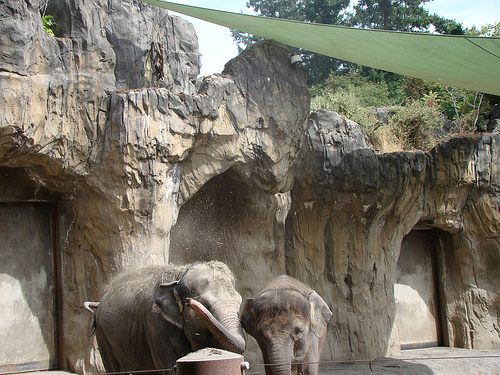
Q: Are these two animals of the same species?
A: Yes, all the animals are elephants.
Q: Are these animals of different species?
A: No, all the animals are elephants.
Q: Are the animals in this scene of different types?
A: No, all the animals are elephants.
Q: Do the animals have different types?
A: No, all the animals are elephants.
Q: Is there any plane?
A: No, there are no airplanes.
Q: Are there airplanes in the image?
A: No, there are no airplanes.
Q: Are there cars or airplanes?
A: No, there are no airplanes or cars.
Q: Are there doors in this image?
A: Yes, there is a door.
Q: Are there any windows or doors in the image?
A: Yes, there is a door.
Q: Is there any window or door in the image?
A: Yes, there is a door.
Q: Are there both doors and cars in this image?
A: No, there is a door but no cars.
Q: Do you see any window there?
A: No, there are no windows.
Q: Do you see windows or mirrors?
A: No, there are no windows or mirrors.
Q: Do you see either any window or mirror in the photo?
A: No, there are no windows or mirrors.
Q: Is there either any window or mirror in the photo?
A: No, there are no windows or mirrors.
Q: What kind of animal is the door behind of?
A: The door is behind the elephant.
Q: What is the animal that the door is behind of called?
A: The animal is an elephant.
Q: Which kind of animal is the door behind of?
A: The door is behind the elephant.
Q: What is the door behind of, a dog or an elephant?
A: The door is behind an elephant.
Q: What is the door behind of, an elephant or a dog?
A: The door is behind an elephant.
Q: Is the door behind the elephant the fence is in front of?
A: Yes, the door is behind the elephant.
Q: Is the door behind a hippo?
A: No, the door is behind the elephant.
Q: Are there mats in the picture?
A: No, there are no mats.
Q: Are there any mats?
A: No, there are no mats.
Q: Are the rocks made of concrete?
A: Yes, the rocks are made of concrete.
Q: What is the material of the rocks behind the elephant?
A: The rocks are made of cement.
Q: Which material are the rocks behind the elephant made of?
A: The rocks are made of cement.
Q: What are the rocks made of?
A: The rocks are made of concrete.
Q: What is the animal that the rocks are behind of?
A: The animal is an elephant.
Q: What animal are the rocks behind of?
A: The rocks are behind the elephant.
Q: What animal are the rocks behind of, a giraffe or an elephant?
A: The rocks are behind an elephant.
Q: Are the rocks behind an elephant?
A: Yes, the rocks are behind an elephant.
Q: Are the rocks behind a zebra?
A: No, the rocks are behind an elephant.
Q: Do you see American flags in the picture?
A: No, there are no American flags.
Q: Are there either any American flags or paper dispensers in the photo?
A: No, there are no American flags or paper dispensers.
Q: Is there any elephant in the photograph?
A: Yes, there is an elephant.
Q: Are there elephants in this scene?
A: Yes, there is an elephant.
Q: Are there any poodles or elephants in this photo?
A: Yes, there is an elephant.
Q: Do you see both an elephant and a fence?
A: Yes, there are both an elephant and a fence.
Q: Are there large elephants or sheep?
A: Yes, there is a large elephant.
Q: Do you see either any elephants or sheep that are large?
A: Yes, the elephant is large.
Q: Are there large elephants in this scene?
A: Yes, there is a large elephant.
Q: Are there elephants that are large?
A: Yes, there is an elephant that is large.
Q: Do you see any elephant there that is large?
A: Yes, there is an elephant that is large.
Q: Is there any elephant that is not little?
A: Yes, there is a large elephant.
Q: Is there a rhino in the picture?
A: No, there are no rhinos.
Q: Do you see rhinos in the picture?
A: No, there are no rhinos.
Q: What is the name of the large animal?
A: The animal is an elephant.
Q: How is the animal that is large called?
A: The animal is an elephant.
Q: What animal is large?
A: The animal is an elephant.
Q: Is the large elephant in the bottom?
A: Yes, the elephant is in the bottom of the image.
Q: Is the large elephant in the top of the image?
A: No, the elephant is in the bottom of the image.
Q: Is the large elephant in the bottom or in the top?
A: The elephant is in the bottom of the image.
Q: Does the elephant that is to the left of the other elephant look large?
A: Yes, the elephant is large.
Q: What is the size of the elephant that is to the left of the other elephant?
A: The elephant is large.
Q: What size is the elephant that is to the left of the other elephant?
A: The elephant is large.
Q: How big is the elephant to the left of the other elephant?
A: The elephant is large.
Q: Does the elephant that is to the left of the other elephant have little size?
A: No, the elephant is large.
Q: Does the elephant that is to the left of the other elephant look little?
A: No, the elephant is large.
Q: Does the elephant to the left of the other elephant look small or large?
A: The elephant is large.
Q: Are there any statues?
A: No, there are no statues.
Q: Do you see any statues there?
A: No, there are no statues.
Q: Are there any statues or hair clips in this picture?
A: No, there are no statues or hair clips.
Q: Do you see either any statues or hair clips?
A: No, there are no statues or hair clips.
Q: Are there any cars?
A: No, there are no cars.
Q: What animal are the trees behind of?
A: The trees are behind the elephant.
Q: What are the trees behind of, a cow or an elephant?
A: The trees are behind an elephant.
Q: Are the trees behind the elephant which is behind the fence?
A: Yes, the trees are behind the elephant.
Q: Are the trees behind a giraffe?
A: No, the trees are behind the elephant.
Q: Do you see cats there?
A: No, there are no cats.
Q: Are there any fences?
A: Yes, there is a fence.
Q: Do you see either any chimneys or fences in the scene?
A: Yes, there is a fence.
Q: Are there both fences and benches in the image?
A: No, there is a fence but no benches.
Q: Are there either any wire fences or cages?
A: Yes, there is a wire fence.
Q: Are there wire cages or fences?
A: Yes, there is a wire fence.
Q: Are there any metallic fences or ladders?
A: Yes, there is a metal fence.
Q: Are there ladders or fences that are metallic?
A: Yes, the fence is metallic.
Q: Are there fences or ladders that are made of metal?
A: Yes, the fence is made of metal.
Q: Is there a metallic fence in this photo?
A: Yes, there is a metal fence.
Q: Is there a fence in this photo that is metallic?
A: Yes, there is a fence that is metallic.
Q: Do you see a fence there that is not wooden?
A: Yes, there is a metallic fence.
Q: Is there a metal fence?
A: Yes, there is a fence that is made of metal.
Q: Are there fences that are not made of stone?
A: Yes, there is a fence that is made of metal.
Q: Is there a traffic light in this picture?
A: No, there are no traffic lights.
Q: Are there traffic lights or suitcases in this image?
A: No, there are no traffic lights or suitcases.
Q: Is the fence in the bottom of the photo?
A: Yes, the fence is in the bottom of the image.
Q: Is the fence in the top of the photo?
A: No, the fence is in the bottom of the image.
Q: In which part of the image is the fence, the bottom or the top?
A: The fence is in the bottom of the image.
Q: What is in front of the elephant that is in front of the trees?
A: The fence is in front of the elephant.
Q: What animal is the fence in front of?
A: The fence is in front of the elephant.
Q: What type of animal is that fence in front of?
A: The fence is in front of the elephant.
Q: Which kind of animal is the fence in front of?
A: The fence is in front of the elephant.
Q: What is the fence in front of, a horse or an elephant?
A: The fence is in front of an elephant.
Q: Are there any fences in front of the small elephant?
A: Yes, there is a fence in front of the elephant.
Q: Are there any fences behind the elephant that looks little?
A: No, the fence is in front of the elephant.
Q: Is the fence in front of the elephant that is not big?
A: Yes, the fence is in front of the elephant.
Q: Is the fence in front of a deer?
A: No, the fence is in front of the elephant.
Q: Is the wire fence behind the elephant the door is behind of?
A: No, the fence is in front of the elephant.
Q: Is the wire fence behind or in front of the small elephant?
A: The fence is in front of the elephant.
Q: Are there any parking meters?
A: No, there are no parking meters.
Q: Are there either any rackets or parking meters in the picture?
A: No, there are no parking meters or rackets.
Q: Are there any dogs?
A: No, there are no dogs.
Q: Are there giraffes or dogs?
A: No, there are no dogs or giraffes.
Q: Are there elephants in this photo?
A: Yes, there is an elephant.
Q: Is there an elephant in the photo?
A: Yes, there is an elephant.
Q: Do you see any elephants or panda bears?
A: Yes, there is an elephant.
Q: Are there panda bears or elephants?
A: Yes, there is an elephant.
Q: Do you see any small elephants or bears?
A: Yes, there is a small elephant.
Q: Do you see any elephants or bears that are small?
A: Yes, the elephant is small.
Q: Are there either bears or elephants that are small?
A: Yes, the elephant is small.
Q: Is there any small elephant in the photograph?
A: Yes, there is a small elephant.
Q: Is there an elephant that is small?
A: Yes, there is an elephant that is small.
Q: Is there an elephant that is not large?
A: Yes, there is a small elephant.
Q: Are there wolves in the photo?
A: No, there are no wolves.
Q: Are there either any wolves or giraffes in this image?
A: No, there are no wolves or giraffes.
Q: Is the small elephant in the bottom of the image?
A: Yes, the elephant is in the bottom of the image.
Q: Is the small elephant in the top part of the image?
A: No, the elephant is in the bottom of the image.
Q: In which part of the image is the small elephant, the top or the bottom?
A: The elephant is in the bottom of the image.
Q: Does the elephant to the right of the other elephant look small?
A: Yes, the elephant is small.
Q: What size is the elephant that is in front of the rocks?
A: The elephant is small.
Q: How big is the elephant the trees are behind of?
A: The elephant is small.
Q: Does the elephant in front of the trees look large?
A: No, the elephant is small.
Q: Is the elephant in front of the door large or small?
A: The elephant is small.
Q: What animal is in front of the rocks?
A: The elephant is in front of the rocks.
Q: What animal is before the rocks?
A: The elephant is in front of the rocks.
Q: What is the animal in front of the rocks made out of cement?
A: The animal is an elephant.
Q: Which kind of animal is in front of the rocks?
A: The animal is an elephant.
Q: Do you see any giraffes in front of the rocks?
A: No, there is an elephant in front of the rocks.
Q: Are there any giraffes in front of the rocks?
A: No, there is an elephant in front of the rocks.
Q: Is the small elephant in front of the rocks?
A: Yes, the elephant is in front of the rocks.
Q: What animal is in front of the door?
A: The elephant is in front of the door.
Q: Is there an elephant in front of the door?
A: Yes, there is an elephant in front of the door.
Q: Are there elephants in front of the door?
A: Yes, there is an elephant in front of the door.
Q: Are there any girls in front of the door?
A: No, there is an elephant in front of the door.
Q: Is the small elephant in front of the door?
A: Yes, the elephant is in front of the door.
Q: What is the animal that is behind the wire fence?
A: The animal is an elephant.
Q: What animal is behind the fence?
A: The animal is an elephant.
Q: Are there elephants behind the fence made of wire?
A: Yes, there is an elephant behind the fence.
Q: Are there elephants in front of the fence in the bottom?
A: No, the elephant is behind the fence.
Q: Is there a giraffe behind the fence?
A: No, there is an elephant behind the fence.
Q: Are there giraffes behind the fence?
A: No, there is an elephant behind the fence.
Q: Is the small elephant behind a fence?
A: Yes, the elephant is behind a fence.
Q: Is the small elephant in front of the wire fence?
A: No, the elephant is behind the fence.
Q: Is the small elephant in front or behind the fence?
A: The elephant is behind the fence.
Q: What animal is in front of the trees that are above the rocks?
A: The elephant is in front of the trees.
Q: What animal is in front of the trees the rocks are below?
A: The elephant is in front of the trees.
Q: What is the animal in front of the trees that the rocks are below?
A: The animal is an elephant.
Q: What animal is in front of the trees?
A: The animal is an elephant.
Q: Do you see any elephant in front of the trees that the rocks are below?
A: Yes, there is an elephant in front of the trees.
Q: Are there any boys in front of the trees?
A: No, there is an elephant in front of the trees.